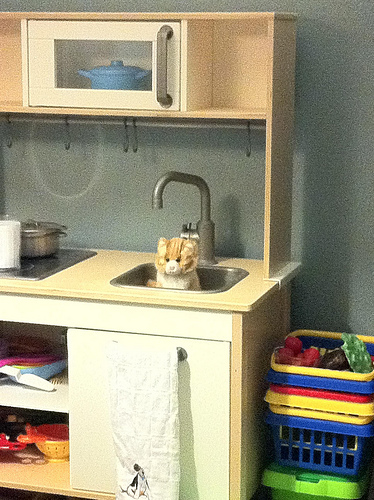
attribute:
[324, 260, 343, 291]
wall — grey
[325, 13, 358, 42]
wall — grey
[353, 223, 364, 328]
wall — grey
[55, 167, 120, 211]
wall — grey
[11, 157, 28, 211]
wall — grey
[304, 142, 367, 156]
wall — grey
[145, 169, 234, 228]
faucet — grey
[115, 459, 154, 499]
dog — white-and-black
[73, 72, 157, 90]
bowl — blue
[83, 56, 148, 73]
lid — blue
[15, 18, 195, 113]
microwave — white-and-grey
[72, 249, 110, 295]
counter — creamy-tan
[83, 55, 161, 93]
teapot — blue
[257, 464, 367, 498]
bin — green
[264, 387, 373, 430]
bins — yellow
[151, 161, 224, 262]
faucet — silver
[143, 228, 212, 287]
animal — stuffed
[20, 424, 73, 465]
strainer — yellow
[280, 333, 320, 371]
tomatoes — plastic